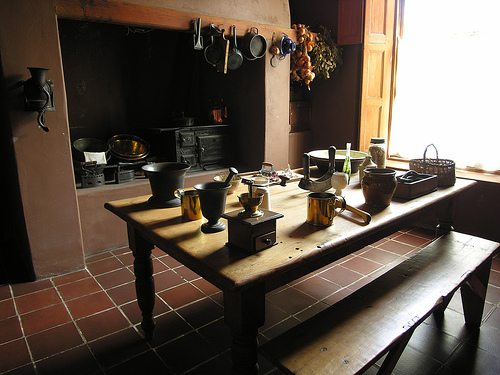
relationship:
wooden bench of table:
[258, 230, 499, 374] [104, 166, 479, 374]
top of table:
[210, 191, 317, 308] [203, 247, 290, 289]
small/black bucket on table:
[138, 158, 192, 210] [100, 153, 483, 290]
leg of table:
[218, 287, 269, 370] [91, 142, 480, 373]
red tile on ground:
[0, 222, 499, 374] [0, 225, 498, 373]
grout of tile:
[71, 320, 88, 345] [63, 288, 117, 321]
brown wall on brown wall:
[0, 7, 92, 285] [0, 0, 289, 279]